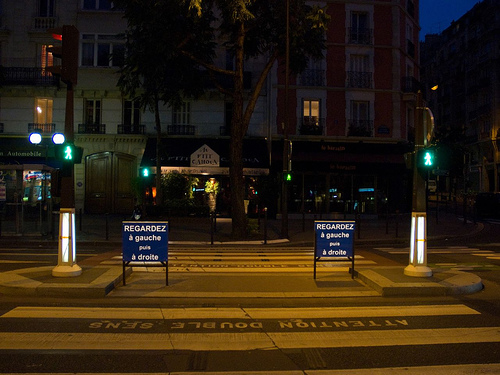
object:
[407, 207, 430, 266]
light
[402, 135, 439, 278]
statue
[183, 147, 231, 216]
statue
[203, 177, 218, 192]
light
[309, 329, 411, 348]
stripe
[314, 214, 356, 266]
sign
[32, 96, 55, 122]
window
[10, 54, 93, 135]
building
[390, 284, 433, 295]
curb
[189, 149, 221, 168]
sign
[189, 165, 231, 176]
awning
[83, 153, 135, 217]
door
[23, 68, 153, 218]
building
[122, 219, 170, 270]
sign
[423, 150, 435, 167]
human figure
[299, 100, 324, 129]
window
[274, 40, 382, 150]
building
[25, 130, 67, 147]
street lamps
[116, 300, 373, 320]
stripe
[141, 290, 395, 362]
street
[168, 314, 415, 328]
words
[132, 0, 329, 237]
tree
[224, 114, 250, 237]
tree trunk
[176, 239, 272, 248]
street curb